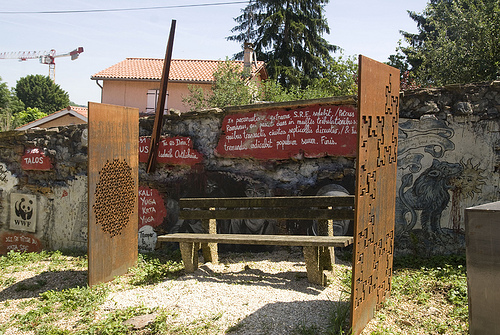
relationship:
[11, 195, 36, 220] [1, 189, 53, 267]
panda on sign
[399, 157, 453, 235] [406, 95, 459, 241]
painting on wall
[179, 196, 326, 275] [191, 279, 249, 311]
bench in sand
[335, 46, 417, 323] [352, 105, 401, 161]
planks have designs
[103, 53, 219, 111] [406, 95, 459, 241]
building behind wall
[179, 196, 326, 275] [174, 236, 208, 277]
bench has legs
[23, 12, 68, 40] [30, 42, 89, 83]
sky has crane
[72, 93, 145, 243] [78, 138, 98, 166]
board has edge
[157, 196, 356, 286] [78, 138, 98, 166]
bench has edge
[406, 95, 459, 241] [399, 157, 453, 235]
wall has painting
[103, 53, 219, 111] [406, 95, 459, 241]
building behind of wall